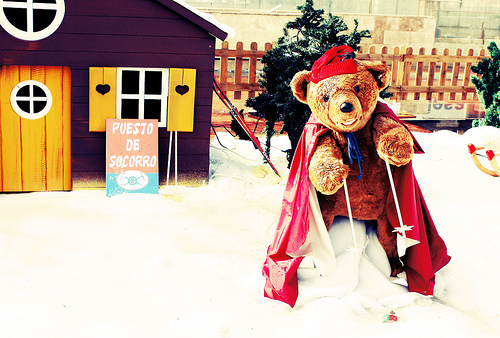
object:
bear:
[284, 44, 419, 334]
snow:
[2, 137, 497, 332]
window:
[115, 68, 170, 126]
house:
[0, 0, 231, 188]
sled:
[485, 149, 500, 176]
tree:
[247, 1, 396, 168]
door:
[1, 65, 71, 192]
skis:
[208, 71, 282, 179]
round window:
[8, 81, 53, 119]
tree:
[468, 40, 499, 132]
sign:
[102, 118, 160, 198]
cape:
[259, 101, 453, 307]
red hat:
[305, 44, 359, 84]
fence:
[213, 40, 498, 106]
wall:
[196, 41, 211, 181]